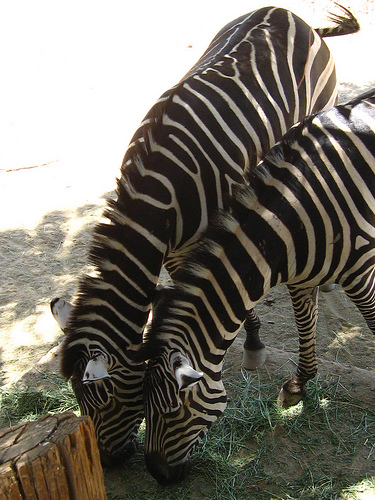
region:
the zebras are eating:
[34, 174, 276, 499]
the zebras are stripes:
[60, 193, 317, 475]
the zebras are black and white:
[43, 176, 306, 497]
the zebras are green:
[225, 407, 266, 478]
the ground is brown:
[9, 249, 55, 334]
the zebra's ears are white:
[44, 286, 138, 404]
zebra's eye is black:
[151, 404, 191, 437]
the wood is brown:
[7, 413, 128, 489]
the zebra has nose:
[114, 417, 217, 497]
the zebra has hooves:
[231, 340, 327, 406]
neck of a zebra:
[183, 281, 241, 342]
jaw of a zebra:
[211, 387, 226, 417]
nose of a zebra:
[155, 464, 170, 485]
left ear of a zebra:
[180, 356, 198, 387]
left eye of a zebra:
[163, 402, 178, 426]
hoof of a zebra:
[265, 376, 299, 407]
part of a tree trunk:
[19, 428, 93, 492]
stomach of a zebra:
[248, 109, 282, 140]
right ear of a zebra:
[48, 298, 72, 316]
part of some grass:
[214, 432, 254, 478]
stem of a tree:
[25, 436, 85, 485]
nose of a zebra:
[140, 455, 170, 482]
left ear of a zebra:
[162, 399, 179, 422]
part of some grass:
[207, 438, 239, 481]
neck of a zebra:
[214, 296, 245, 336]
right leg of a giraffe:
[300, 304, 323, 338]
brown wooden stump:
[0, 405, 111, 497]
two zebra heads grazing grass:
[40, 303, 235, 493]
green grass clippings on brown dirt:
[248, 421, 343, 495]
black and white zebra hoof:
[268, 347, 334, 419]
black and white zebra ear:
[163, 343, 212, 398]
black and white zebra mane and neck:
[144, 236, 272, 360]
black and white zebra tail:
[308, 1, 368, 50]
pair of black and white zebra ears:
[32, 280, 114, 395]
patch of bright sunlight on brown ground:
[10, 296, 64, 349]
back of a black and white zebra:
[120, 1, 310, 154]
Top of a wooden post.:
[1, 411, 107, 498]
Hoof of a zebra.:
[278, 377, 304, 407]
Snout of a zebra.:
[144, 453, 191, 486]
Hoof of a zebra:
[241, 346, 267, 370]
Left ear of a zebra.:
[172, 351, 204, 390]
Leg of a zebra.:
[284, 283, 320, 391]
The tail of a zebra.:
[310, 3, 360, 37]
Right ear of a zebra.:
[48, 296, 73, 328]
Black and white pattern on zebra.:
[274, 170, 347, 272]